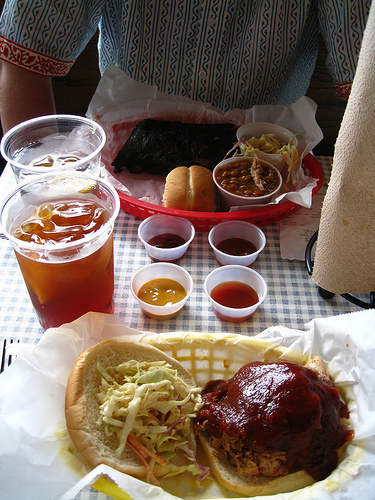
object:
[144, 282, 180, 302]
mustard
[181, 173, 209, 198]
top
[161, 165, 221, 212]
bun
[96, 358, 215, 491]
coleslaw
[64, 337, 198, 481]
bun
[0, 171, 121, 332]
cup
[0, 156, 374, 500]
table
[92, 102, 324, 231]
basket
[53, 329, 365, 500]
basket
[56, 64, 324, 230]
paper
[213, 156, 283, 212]
dish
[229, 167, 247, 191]
beans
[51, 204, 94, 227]
ice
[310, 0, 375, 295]
paper towel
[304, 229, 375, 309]
rack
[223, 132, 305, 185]
coleslaw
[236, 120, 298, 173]
dish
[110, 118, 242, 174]
meat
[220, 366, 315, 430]
sauce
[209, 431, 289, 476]
meat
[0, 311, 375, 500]
paper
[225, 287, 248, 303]
sauce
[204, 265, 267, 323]
container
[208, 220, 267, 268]
cup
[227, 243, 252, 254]
sauce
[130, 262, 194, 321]
containers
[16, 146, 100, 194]
drinks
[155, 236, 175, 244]
sauces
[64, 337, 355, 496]
sandwich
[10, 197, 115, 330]
drink